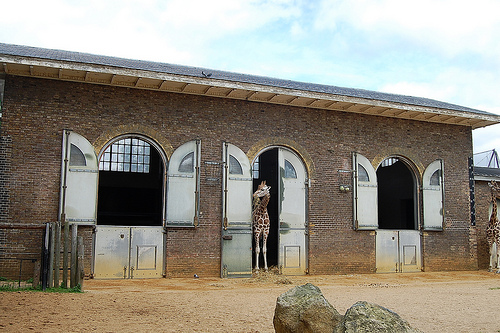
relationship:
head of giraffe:
[250, 176, 273, 208] [252, 180, 270, 274]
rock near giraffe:
[273, 283, 345, 332] [252, 180, 270, 274]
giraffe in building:
[252, 180, 270, 274] [1, 37, 494, 283]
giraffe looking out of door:
[252, 180, 270, 274] [216, 139, 255, 281]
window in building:
[89, 135, 168, 175] [86, 69, 211, 107]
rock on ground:
[267, 279, 400, 331] [5, 270, 499, 333]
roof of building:
[1, 39, 498, 144] [1, 37, 494, 283]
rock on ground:
[341, 301, 417, 331] [5, 270, 499, 333]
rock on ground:
[273, 283, 345, 332] [5, 270, 499, 333]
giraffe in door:
[252, 180, 270, 274] [350, 152, 379, 232]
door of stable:
[342, 137, 463, 299] [0, 35, 480, 288]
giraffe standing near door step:
[252, 178, 272, 274] [55, 268, 499, 291]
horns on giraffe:
[257, 180, 262, 186] [252, 180, 270, 274]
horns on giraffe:
[262, 180, 269, 186] [252, 180, 270, 274]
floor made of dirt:
[117, 277, 492, 284] [271, 276, 291, 283]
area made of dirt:
[0, 272, 499, 333] [34, 259, 484, 332]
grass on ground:
[1, 278, 71, 302] [5, 270, 499, 333]